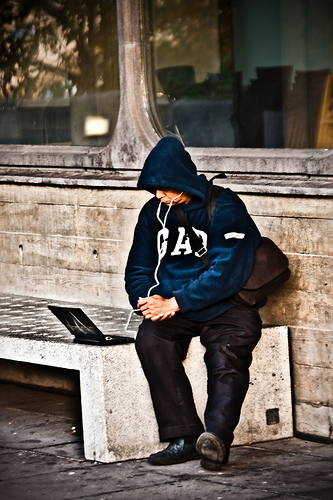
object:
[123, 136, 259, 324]
hoodie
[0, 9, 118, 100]
reflection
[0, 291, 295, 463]
bench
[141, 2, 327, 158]
window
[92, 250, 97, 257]
hole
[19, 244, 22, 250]
hole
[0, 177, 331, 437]
wall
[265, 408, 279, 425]
hole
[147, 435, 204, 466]
shoes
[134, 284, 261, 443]
pants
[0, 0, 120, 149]
window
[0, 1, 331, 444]
building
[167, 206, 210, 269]
strap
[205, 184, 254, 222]
shoulder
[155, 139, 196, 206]
head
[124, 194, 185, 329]
cable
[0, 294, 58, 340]
surface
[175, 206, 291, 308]
satchel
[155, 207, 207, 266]
chest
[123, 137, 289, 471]
man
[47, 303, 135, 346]
electronic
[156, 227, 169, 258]
letter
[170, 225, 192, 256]
letter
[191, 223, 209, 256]
letter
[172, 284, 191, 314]
sleeves